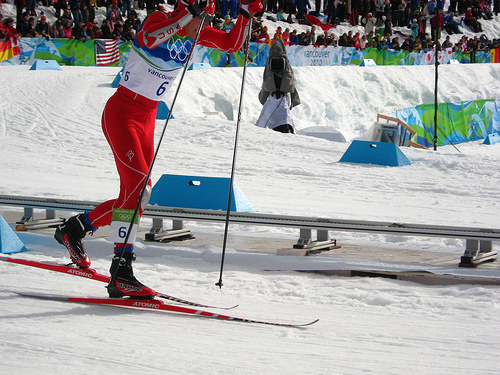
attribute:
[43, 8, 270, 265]
man — red, tall, skiing, white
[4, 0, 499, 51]
crowd — far, watching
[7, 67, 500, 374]
snow — white, colored, deep, big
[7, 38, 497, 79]
wall — blue, short, red, white, green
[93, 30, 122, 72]
flag — USA flag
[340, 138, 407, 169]
block — blue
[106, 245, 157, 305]
boot — ski boot, red, black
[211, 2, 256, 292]
pole — ski pole , long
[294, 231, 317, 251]
support — one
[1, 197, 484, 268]
track — metal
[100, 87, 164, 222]
pants — red, bright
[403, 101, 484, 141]
tube — yellow, twisty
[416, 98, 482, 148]
tarp — green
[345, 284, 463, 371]
snow — white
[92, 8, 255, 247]
suit — sports suit, red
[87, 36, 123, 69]
flag — American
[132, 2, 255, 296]
poles — ski poles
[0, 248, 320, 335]
skis — red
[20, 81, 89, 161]
tracks — ski tracks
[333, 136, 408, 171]
ramp — small, blue, light, snow ramp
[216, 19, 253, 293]
pole — ski pole, metal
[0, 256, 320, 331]
ski — pair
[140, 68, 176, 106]
card — number